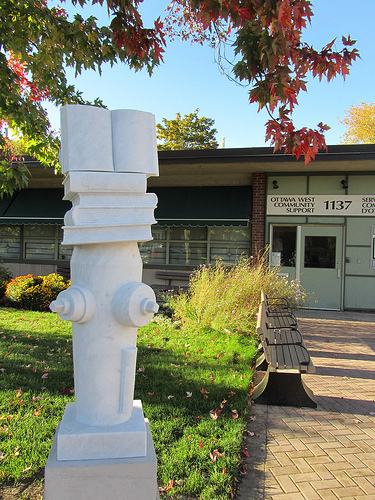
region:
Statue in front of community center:
[48, 104, 166, 495]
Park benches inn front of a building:
[251, 289, 319, 406]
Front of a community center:
[3, 147, 372, 309]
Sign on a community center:
[264, 195, 373, 214]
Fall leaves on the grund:
[174, 330, 255, 493]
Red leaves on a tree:
[264, 76, 328, 162]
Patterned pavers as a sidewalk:
[323, 319, 371, 495]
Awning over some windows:
[2, 182, 253, 231]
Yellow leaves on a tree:
[345, 101, 374, 140]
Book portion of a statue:
[54, 102, 163, 243]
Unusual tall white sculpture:
[50, 97, 155, 495]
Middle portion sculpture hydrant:
[55, 248, 160, 412]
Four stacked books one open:
[52, 103, 161, 254]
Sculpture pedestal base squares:
[40, 401, 165, 497]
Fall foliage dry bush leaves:
[167, 266, 255, 484]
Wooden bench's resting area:
[257, 285, 322, 416]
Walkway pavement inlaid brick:
[309, 311, 370, 485]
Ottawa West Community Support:
[267, 190, 323, 216]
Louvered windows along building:
[155, 224, 251, 270]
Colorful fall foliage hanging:
[202, 0, 348, 163]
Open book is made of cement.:
[57, 119, 161, 175]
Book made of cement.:
[56, 210, 159, 245]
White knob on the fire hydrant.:
[126, 292, 157, 322]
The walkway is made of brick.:
[305, 448, 356, 473]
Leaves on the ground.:
[200, 401, 235, 424]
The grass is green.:
[164, 456, 206, 480]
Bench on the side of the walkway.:
[255, 305, 318, 342]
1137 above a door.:
[311, 198, 361, 219]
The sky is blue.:
[165, 73, 211, 102]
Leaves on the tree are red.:
[274, 131, 331, 160]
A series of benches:
[235, 283, 331, 411]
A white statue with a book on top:
[34, 98, 169, 493]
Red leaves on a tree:
[164, 0, 360, 175]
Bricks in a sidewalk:
[250, 407, 373, 498]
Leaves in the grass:
[167, 351, 233, 430]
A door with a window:
[294, 217, 346, 318]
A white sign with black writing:
[259, 191, 373, 222]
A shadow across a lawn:
[0, 312, 278, 425]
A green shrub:
[158, 245, 308, 342]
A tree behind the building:
[155, 105, 224, 156]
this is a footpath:
[292, 416, 361, 497]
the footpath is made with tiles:
[293, 424, 335, 480]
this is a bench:
[260, 289, 307, 407]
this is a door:
[294, 229, 344, 305]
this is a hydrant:
[57, 102, 153, 495]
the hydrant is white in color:
[69, 113, 124, 193]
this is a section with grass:
[181, 392, 208, 431]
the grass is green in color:
[171, 406, 197, 454]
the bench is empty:
[262, 294, 301, 372]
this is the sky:
[174, 56, 209, 84]